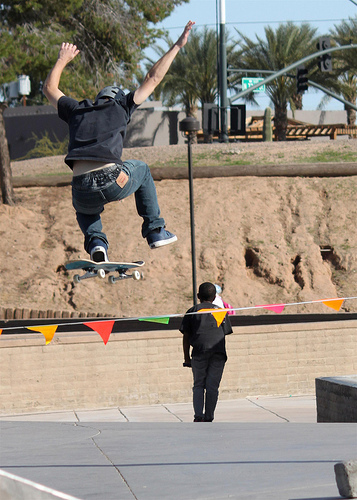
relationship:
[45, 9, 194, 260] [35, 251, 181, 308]
boy performs on skateboard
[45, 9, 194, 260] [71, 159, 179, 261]
boy wears jeans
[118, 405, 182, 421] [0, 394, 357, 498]
square on concrete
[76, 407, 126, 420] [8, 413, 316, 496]
square on concrete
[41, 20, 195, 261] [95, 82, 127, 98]
boy on helmet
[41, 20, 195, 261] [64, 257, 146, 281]
boy on skateboard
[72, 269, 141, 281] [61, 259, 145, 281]
white wheels on skateboard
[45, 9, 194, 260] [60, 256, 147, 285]
boy on skateboard